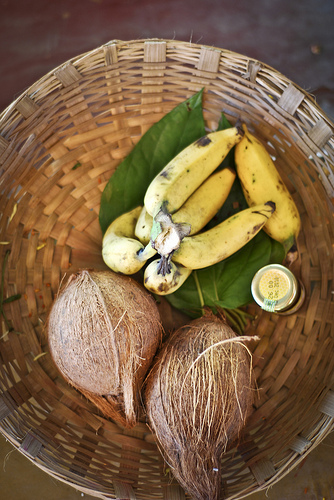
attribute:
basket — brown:
[1, 31, 333, 306]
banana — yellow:
[229, 123, 313, 253]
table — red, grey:
[224, 8, 308, 48]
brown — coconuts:
[65, 295, 134, 356]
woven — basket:
[83, 60, 135, 109]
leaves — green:
[154, 125, 182, 148]